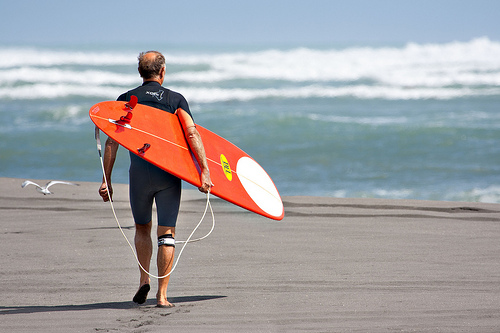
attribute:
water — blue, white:
[5, 46, 495, 198]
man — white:
[87, 49, 228, 304]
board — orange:
[92, 96, 289, 227]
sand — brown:
[7, 175, 490, 332]